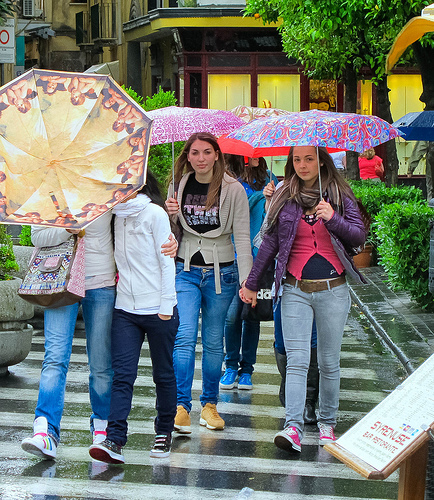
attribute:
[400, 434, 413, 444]
letter — red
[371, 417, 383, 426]
letter — red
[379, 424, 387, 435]
letter — red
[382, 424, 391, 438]
letter — red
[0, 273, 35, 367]
flower pot — FLOWER 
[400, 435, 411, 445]
letter — red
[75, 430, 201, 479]
sneakers — HER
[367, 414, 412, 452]
letter — red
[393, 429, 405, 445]
letter — red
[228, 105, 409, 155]
umbrella — HER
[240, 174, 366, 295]
jacket — purple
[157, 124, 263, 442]
woman — mouth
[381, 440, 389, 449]
letter — red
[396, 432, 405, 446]
letter — red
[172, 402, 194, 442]
shoe — brown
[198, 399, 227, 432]
shoe — brown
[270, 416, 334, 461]
shoes — pink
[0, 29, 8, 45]
letter — red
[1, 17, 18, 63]
sign — red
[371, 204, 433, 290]
leaves — green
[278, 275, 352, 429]
pants — grey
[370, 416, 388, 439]
letter — red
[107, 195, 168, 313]
sweater — white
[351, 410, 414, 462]
letter — red